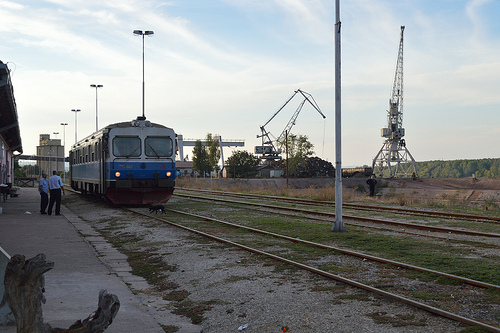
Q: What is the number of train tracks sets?
A: 3.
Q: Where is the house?
A: Behind the train in the distance.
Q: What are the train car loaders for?
A: Grain, coal, rock.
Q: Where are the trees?
A: Near the house behind the train.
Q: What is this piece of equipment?
A: Loads train cars.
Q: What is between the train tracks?
A: Dirt, gravel, grass.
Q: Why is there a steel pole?
A: Lights.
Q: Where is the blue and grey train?
A: Stopped on track.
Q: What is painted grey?
A: Metal light pole.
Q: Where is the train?
A: On the tracks.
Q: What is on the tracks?
A: A train.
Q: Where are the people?
A: Outside the train.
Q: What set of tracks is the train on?
A: The left set.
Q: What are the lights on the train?
A: Headlights.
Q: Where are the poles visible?
A: On the right.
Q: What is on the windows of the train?
A: Windshield wipers.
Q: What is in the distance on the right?
A: Trees.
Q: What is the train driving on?
A: Tracks.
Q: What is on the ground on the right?
A: Tracks.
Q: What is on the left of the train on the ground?
A: Dirt.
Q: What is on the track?
A: A train.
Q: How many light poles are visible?
A: Six.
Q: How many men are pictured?
A: Two.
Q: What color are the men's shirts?
A: Blue.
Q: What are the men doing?
A: Talking.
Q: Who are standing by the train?
A: The two men.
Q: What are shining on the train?
A: Lights.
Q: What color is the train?
A: Blue.